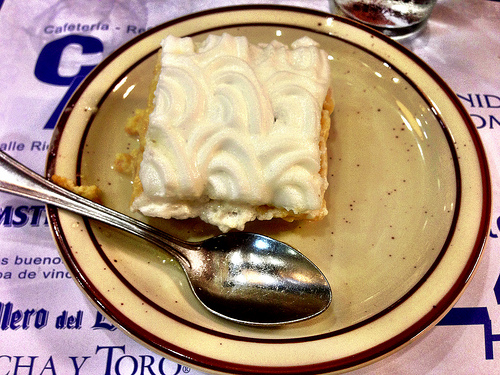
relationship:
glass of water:
[335, 1, 434, 40] [354, 3, 424, 21]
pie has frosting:
[132, 34, 337, 233] [144, 34, 327, 201]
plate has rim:
[43, 5, 489, 373] [476, 112, 494, 283]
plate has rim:
[43, 5, 489, 373] [179, 361, 376, 373]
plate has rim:
[43, 5, 489, 373] [57, 220, 85, 296]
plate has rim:
[43, 5, 489, 373] [174, 2, 344, 15]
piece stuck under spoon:
[51, 170, 105, 202] [1, 149, 334, 328]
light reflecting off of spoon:
[227, 241, 289, 293] [1, 149, 334, 328]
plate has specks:
[43, 5, 489, 373] [376, 102, 419, 162]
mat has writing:
[3, 3, 498, 374] [3, 299, 89, 375]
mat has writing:
[3, 3, 498, 374] [3, 206, 41, 286]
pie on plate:
[132, 34, 337, 233] [43, 5, 489, 373]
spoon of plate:
[1, 149, 334, 328] [43, 5, 489, 373]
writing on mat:
[3, 345, 181, 374] [3, 3, 498, 374]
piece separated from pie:
[51, 170, 105, 202] [132, 34, 337, 233]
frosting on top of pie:
[144, 34, 327, 201] [132, 34, 337, 233]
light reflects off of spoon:
[227, 241, 289, 293] [1, 149, 334, 328]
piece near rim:
[51, 170, 105, 202] [57, 220, 85, 296]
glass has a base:
[335, 1, 434, 40] [360, 22, 432, 40]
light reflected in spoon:
[227, 241, 289, 293] [1, 149, 334, 328]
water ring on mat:
[23, 0, 153, 60] [3, 3, 498, 374]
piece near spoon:
[51, 170, 105, 202] [1, 149, 334, 328]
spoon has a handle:
[1, 149, 334, 328] [1, 146, 179, 264]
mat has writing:
[3, 3, 498, 374] [40, 18, 116, 33]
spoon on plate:
[1, 149, 334, 328] [43, 5, 489, 373]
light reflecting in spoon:
[227, 241, 289, 293] [1, 149, 334, 328]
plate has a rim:
[43, 5, 489, 373] [476, 112, 494, 283]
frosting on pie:
[144, 34, 327, 201] [132, 34, 337, 233]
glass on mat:
[335, 1, 434, 40] [3, 3, 498, 374]